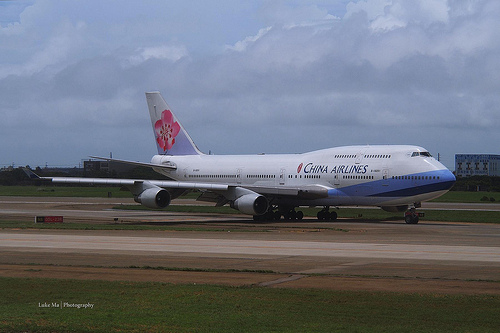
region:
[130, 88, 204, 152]
tail of the airplane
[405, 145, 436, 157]
windshield of the plane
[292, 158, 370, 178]
plane is for china airlines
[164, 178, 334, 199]
wing of the plane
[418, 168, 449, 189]
nose of the plane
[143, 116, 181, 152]
flower on plane tail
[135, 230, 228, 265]
dirt on the ground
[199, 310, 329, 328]
grass on the ground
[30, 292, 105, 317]
the photographer's watermark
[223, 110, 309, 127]
clouds in the sky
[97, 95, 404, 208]
white and blue plane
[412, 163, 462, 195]
blue stripes on nose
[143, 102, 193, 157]
pink flower on tail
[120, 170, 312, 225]
white engines on plane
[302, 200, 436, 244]
black wheels on plane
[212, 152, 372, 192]
long row of small windows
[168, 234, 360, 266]
runway is light brown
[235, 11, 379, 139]
blue and white sky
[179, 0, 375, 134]
layered white clouds in sky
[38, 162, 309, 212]
white wing on plane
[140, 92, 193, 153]
tail of the airplane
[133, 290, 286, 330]
a field of green grass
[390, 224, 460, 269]
the roadway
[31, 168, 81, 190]
wing of the airplane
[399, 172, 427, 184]
windows on the airplane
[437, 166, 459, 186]
nose of the airplane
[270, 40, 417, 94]
clouds in the sky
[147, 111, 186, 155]
a pink flower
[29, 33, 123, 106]
the clouds are white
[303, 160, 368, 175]
writing on the airplane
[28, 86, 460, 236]
An airplane stationed at an airport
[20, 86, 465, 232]
An airplane stationed at an airport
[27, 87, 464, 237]
An airplane stationed at an airport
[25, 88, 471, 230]
An airplane stationed at an airport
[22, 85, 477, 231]
An airplane stationed at an airport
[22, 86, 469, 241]
An airplane stationed at an airport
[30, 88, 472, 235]
An airplane stationed at an airport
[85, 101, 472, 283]
a plane on the ground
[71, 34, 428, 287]
an airplane on the ground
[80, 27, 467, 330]
a white plane on the ground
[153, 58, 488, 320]
a white airplane on the ground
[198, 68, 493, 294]
a large plane on the ground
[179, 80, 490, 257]
a passenger airplane on the ground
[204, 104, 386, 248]
a large plane on the ground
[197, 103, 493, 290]
a large airplane on the ground